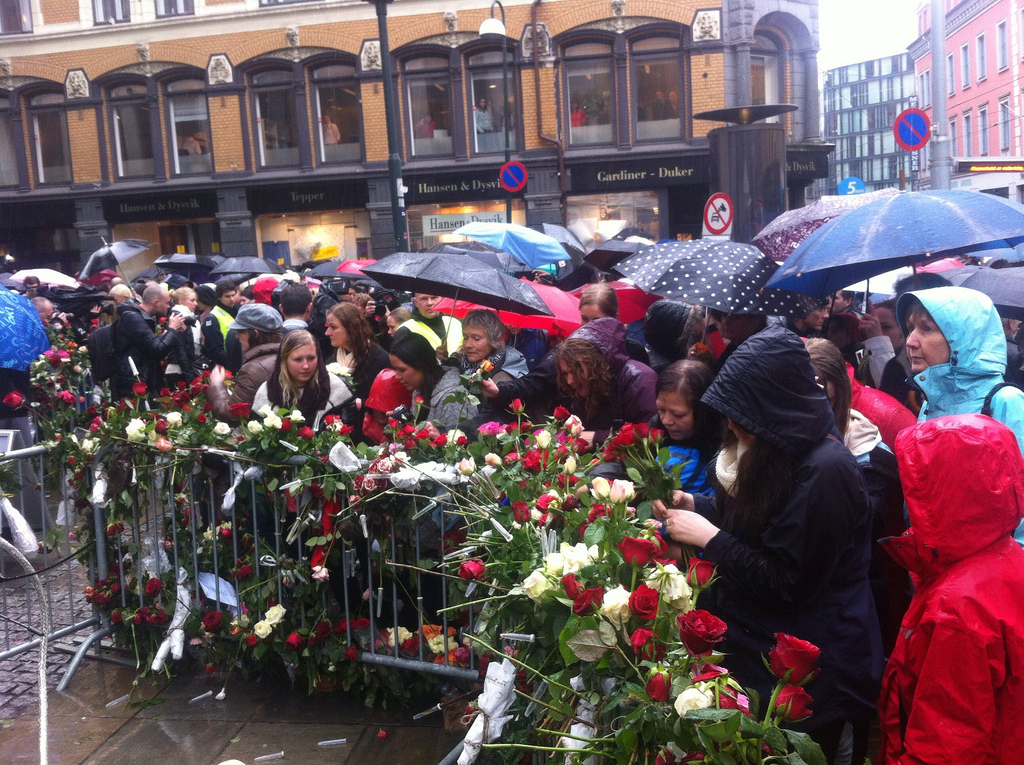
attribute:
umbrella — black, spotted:
[603, 233, 831, 333]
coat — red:
[879, 408, 1022, 762]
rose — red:
[293, 424, 324, 450]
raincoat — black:
[700, 322, 890, 742]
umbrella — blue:
[762, 175, 1021, 309]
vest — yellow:
[400, 311, 468, 361]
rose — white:
[214, 414, 232, 439]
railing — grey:
[78, 422, 691, 756]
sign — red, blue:
[491, 156, 538, 193]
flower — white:
[88, 472, 114, 521]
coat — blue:
[894, 282, 1023, 550]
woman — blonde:
[169, 285, 207, 318]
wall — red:
[903, 2, 1006, 178]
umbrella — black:
[353, 251, 558, 328]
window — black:
[545, 23, 707, 165]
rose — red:
[507, 398, 532, 417]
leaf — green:
[322, 638, 344, 663]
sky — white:
[816, 2, 942, 160]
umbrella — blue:
[8, 282, 62, 383]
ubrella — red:
[423, 282, 614, 350]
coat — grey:
[436, 341, 538, 393]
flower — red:
[297, 427, 323, 445]